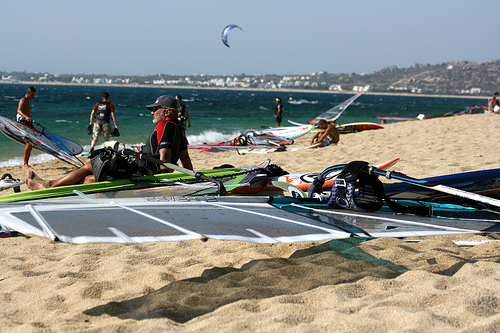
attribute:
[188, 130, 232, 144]
wave — white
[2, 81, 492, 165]
water — turquoise, choppy, blue, green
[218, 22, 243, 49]
kite — silver, blue, white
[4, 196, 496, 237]
surfboard — white, gray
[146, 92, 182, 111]
cap — gray, white, black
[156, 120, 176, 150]
sleeve — red, black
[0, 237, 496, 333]
sand — brown, tan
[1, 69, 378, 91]
houses — white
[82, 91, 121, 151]
man — walking, standing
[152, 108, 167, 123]
beard — white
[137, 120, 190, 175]
wetsuit — red, black, gray, black,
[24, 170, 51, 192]
feet — bare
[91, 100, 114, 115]
shirt — red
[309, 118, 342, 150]
man — sitting